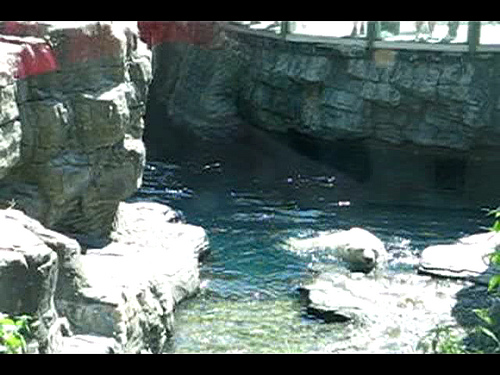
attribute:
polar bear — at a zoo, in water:
[290, 228, 386, 269]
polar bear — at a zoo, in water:
[286, 223, 392, 281]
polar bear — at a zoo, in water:
[292, 220, 389, 273]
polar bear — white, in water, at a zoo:
[285, 222, 388, 270]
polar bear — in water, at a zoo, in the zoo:
[288, 223, 390, 273]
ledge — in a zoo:
[120, 203, 204, 305]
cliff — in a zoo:
[71, 44, 155, 205]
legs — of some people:
[406, 20, 485, 44]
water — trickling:
[183, 182, 326, 267]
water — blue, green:
[189, 272, 314, 354]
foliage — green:
[0, 308, 30, 356]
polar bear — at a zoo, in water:
[289, 220, 390, 277]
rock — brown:
[2, 53, 145, 242]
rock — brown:
[151, 24, 495, 144]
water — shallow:
[189, 290, 308, 350]